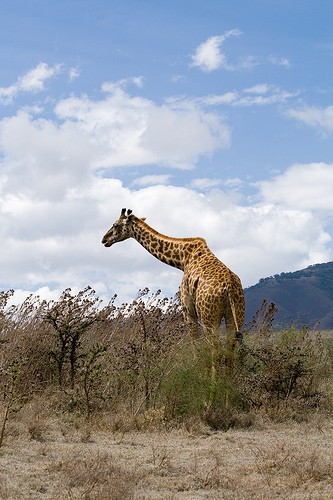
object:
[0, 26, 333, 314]
white clouds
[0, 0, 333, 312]
blue sky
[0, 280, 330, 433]
weeds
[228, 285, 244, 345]
tail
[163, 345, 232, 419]
brush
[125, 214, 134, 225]
ear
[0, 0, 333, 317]
cloud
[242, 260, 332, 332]
hill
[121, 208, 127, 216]
horn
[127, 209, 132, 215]
horn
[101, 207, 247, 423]
giraffe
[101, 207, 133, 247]
head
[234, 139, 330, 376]
distance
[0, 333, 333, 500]
field